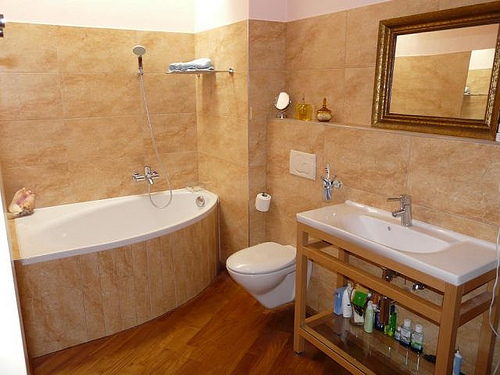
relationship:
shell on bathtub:
[6, 186, 36, 214] [12, 186, 224, 327]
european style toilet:
[227, 236, 315, 317] [231, 235, 310, 305]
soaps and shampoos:
[400, 317, 430, 352] [361, 299, 374, 334]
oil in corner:
[288, 95, 337, 127] [255, 17, 322, 130]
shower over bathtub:
[130, 43, 153, 92] [12, 186, 224, 327]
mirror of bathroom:
[379, 19, 494, 118] [4, 4, 441, 274]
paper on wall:
[256, 193, 273, 215] [248, 27, 276, 247]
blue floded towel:
[196, 63, 206, 71] [168, 55, 214, 80]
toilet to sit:
[231, 235, 310, 305] [228, 236, 276, 274]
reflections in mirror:
[458, 80, 488, 109] [379, 19, 494, 118]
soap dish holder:
[325, 188, 331, 203] [317, 164, 335, 203]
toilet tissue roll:
[231, 235, 310, 305] [250, 190, 277, 216]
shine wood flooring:
[167, 329, 189, 352] [188, 310, 282, 368]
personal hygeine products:
[335, 288, 351, 323] [331, 281, 392, 341]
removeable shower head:
[136, 69, 146, 79] [128, 39, 158, 84]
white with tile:
[89, 210, 111, 233] [167, 258, 205, 289]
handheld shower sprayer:
[136, 57, 142, 77] [131, 42, 152, 60]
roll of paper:
[250, 190, 277, 216] [256, 193, 273, 215]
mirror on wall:
[379, 19, 494, 118] [248, 27, 276, 247]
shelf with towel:
[166, 70, 234, 80] [168, 55, 214, 80]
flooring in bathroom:
[188, 310, 282, 368] [4, 4, 441, 274]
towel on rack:
[168, 55, 214, 80] [199, 67, 235, 80]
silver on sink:
[403, 202, 407, 209] [341, 193, 450, 268]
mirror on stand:
[379, 19, 494, 118] [276, 109, 284, 119]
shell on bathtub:
[8, 186, 37, 224] [12, 186, 224, 327]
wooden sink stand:
[296, 225, 305, 238] [276, 109, 284, 119]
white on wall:
[89, 210, 111, 233] [248, 27, 276, 247]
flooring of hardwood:
[28, 266, 354, 374] [221, 316, 251, 340]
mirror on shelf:
[379, 19, 494, 118] [166, 70, 234, 80]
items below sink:
[324, 277, 404, 329] [341, 193, 450, 268]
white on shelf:
[89, 210, 111, 233] [166, 70, 234, 80]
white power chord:
[89, 210, 111, 233] [147, 138, 168, 164]